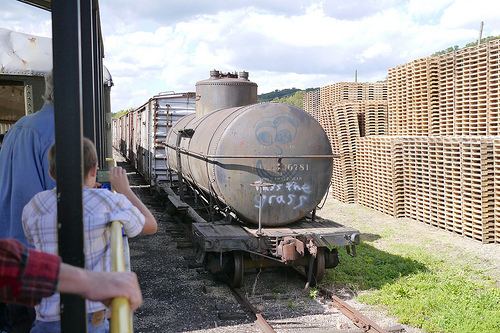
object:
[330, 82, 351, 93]
pallets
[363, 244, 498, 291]
railroad side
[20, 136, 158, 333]
boy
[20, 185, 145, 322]
shirt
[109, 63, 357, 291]
train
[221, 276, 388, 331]
tracks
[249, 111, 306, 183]
graffiti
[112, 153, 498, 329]
ground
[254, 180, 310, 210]
graffiti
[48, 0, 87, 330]
pole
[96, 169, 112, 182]
phone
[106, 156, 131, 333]
rail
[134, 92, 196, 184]
boxcar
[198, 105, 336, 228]
metal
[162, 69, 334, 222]
tank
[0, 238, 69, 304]
shirt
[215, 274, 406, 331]
tracks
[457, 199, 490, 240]
pallet stack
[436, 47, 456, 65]
pallet stack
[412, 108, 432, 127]
pallet stack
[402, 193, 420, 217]
pallet stack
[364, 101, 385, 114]
pallet stack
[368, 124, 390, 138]
wood pallets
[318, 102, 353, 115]
pallet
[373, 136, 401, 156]
pallet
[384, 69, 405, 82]
pallet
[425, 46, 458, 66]
pallet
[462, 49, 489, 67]
pallet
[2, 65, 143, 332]
group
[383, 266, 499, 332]
patch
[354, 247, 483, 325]
grass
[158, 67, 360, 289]
car